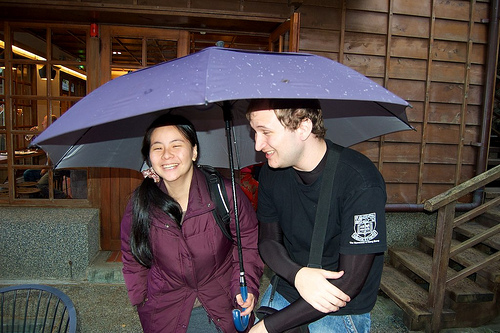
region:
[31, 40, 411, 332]
A couple are standing under an umbrella.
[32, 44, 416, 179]
The umbrella is purple.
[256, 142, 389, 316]
The man is wearing a black shirt.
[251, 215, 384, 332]
The man is wearing arm covers.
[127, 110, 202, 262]
The girl has black hair.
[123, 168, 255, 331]
The girl is wearing a purple coat.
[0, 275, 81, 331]
A chair is off to the side.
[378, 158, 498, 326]
Some stairs behind the couple.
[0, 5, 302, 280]
A shop is behind the couple.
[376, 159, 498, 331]
The stairs are made of wood.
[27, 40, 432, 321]
Two young people sharing an umbrella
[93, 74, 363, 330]
two people are walking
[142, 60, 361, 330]
two people sharing the same umbrella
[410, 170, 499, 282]
the stairs are made of wood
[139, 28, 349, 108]
th umbrella is white in color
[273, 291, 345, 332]
the man pants are faded blue in color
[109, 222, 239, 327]
the jacket is moarron in color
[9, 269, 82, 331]
the seat is mettalic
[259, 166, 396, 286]
the sweater is black in color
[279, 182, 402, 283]
the sweaytr has a white logo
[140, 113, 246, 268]
the lady is smiling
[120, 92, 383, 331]
a man and a womam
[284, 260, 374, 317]
hand on the elbow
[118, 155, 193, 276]
black hair laying over the shoulder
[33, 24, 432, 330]
two people under an umbrella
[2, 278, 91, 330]
top of a chair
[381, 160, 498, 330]
a set of stairs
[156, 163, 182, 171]
smiles on the face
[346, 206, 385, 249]
logo on the sleeve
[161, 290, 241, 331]
bottom of the jacket is open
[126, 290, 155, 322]
hand in the pocket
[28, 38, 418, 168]
A navy blue umbrella two people are under.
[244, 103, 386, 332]
A brown haired man smiling in a black shirt.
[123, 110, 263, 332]
A black haired woman smiling in a purple coat.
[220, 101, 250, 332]
A long silver umbrella pole with blue handle.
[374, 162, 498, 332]
Five wooden stairs going up with wood railing.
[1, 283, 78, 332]
The top of a black metal chair.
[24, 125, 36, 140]
A clear bottle of water through a glass window.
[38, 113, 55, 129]
Bald head of a man through the glass.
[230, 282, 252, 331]
Blue J looking umbrella handle.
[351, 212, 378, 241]
A white logo on a man's black shirt.